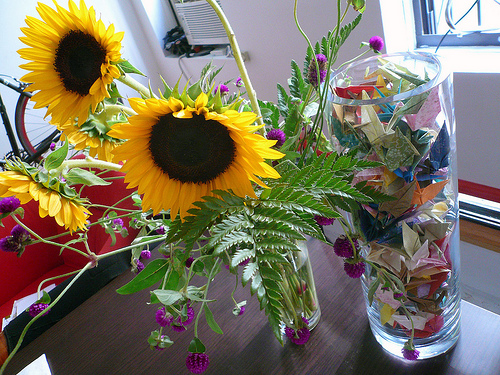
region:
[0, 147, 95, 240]
the sun flower to the left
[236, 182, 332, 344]
the vase to the left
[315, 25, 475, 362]
the vase to the right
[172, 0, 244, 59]
an air conditioner unit in the window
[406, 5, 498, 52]
the window behind the vase to the right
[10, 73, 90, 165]
a bicycle wheel behind the flowers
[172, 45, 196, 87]
the cord to the air conditioner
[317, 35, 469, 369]
a vase sitting on a brown table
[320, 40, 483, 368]
a vase filled with origami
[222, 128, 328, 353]
a vase filled with flowers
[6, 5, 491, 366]
a table top with flowers and a glass vase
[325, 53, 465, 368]
a glass vase filled with origami cranes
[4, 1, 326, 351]
a flower arrangement in a glass bottle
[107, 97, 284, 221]
a yellow sunflower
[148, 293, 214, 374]
small and round purple flowers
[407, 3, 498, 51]
a window with sunlight coming through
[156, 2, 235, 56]
a white air conditioning unit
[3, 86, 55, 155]
a bike tire with metal spokes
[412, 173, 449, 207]
an orange origami paper crane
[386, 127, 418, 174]
a green origami paper crane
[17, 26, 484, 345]
Picture taken indoors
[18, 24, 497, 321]
picture taken during the day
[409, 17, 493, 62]
light is coming in through the window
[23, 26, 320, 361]
flowers in a vase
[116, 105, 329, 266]
the flowers have yellow petals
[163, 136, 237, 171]
the middle of the flowers are black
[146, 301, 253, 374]
the flowers have purple petals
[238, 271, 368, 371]
the vase is on a table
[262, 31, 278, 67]
the walls are painted white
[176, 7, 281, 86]
a window air conditioner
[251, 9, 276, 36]
this is the wall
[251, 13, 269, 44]
the wall is white in color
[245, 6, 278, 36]
the wall is clean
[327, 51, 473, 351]
this is a vase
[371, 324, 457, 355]
the vase is made of glass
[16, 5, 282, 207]
these are two sunflowers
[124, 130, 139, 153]
the leaves are yellow in color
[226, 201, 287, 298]
these are some leaves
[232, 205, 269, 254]
the leaves are green in color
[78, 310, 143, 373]
this is a table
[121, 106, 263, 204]
a yellow flower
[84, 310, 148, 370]
a brown table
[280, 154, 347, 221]
green leaves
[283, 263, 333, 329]
a clear vase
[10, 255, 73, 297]
the couch is red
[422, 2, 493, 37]
a window with light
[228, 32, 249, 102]
a green stem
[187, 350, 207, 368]
a purple flower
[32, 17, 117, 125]
a yellow daisy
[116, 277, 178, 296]
a green leaf